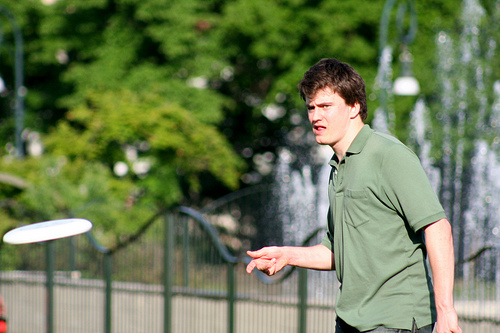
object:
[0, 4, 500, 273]
trees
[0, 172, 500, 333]
fence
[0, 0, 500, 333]
background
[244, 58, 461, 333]
man